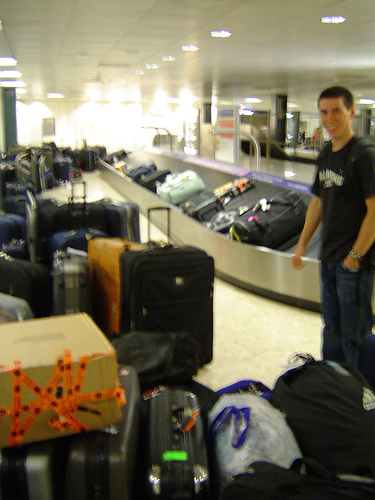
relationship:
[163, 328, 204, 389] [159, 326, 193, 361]
bag has edge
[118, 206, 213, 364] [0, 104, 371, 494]
luggage in baggage claim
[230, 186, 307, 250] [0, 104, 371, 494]
luggage in baggage claim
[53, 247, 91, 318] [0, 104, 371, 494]
luggage in baggage claim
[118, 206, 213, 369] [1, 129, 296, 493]
luggage in baggage claim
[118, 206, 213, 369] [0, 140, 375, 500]
luggage in baggage claim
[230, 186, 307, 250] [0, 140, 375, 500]
luggage in baggage claim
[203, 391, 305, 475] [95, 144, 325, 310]
luggage in baggage claim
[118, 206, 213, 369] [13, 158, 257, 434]
luggage in baggage claim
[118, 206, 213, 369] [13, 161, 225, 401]
luggage in baggage claim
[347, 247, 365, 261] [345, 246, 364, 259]
watch on wrist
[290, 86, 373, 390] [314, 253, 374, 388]
man wearing jeans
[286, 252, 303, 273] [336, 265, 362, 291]
hand in pocket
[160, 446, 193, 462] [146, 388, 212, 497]
tag on top of black suitcase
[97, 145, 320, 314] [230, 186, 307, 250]
carousel taking luggage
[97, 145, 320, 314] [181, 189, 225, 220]
carousel taking luggage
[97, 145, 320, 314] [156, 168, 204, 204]
carousel taking luggage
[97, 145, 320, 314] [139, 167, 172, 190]
carousel taking luggage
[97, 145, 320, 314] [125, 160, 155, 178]
carousel taking luggage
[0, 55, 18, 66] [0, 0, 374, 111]
light built into ceiling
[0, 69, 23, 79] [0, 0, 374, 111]
light built into ceiling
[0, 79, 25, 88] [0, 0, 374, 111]
light built into ceiling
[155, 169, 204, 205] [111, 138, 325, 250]
luggage laying on carousel